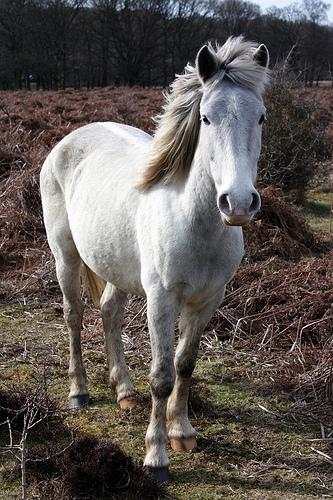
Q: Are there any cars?
A: No, there are no cars.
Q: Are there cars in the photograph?
A: No, there are no cars.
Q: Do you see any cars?
A: No, there are no cars.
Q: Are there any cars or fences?
A: No, there are no cars or fences.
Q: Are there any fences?
A: No, there are no fences.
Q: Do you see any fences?
A: No, there are no fences.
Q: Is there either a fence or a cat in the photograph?
A: No, there are no fences or cats.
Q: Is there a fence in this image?
A: No, there are no fences.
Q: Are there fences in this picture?
A: No, there are no fences.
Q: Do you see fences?
A: No, there are no fences.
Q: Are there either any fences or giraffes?
A: No, there are no fences or giraffes.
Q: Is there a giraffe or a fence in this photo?
A: No, there are no fences or giraffes.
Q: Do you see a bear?
A: No, there are no bears.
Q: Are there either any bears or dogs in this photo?
A: No, there are no bears or dogs.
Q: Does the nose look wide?
A: Yes, the nose is wide.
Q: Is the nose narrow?
A: No, the nose is wide.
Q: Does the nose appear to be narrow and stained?
A: No, the nose is stained but wide.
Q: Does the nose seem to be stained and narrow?
A: No, the nose is stained but wide.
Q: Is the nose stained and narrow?
A: No, the nose is stained but wide.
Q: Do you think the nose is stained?
A: Yes, the nose is stained.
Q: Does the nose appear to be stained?
A: Yes, the nose is stained.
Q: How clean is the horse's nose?
A: The nose is stained.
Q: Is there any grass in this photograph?
A: Yes, there is grass.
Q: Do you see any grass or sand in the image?
A: Yes, there is grass.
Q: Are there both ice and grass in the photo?
A: No, there is grass but no ice.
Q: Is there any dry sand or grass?
A: Yes, there is dry grass.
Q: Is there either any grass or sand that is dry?
A: Yes, the grass is dry.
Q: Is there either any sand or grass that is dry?
A: Yes, the grass is dry.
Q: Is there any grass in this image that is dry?
A: Yes, there is dry grass.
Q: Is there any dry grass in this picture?
A: Yes, there is dry grass.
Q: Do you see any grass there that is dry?
A: Yes, there is grass that is dry.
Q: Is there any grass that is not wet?
A: Yes, there is dry grass.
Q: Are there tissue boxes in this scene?
A: No, there are no tissue boxes.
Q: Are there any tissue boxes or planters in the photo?
A: No, there are no tissue boxes or planters.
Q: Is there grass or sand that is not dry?
A: No, there is grass but it is dry.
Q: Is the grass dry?
A: Yes, the grass is dry.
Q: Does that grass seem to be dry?
A: Yes, the grass is dry.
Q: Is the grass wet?
A: No, the grass is dry.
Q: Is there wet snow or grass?
A: No, there is grass but it is dry.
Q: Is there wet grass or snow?
A: No, there is grass but it is dry.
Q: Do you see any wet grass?
A: No, there is grass but it is dry.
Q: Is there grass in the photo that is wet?
A: No, there is grass but it is dry.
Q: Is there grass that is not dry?
A: No, there is grass but it is dry.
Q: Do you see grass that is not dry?
A: No, there is grass but it is dry.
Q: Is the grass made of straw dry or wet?
A: The grass is dry.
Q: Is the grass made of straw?
A: Yes, the grass is made of straw.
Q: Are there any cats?
A: No, there are no cats.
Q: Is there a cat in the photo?
A: No, there are no cats.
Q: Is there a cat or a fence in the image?
A: No, there are no cats or fences.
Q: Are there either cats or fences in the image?
A: No, there are no cats or fences.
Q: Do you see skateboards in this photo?
A: No, there are no skateboards.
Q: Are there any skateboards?
A: No, there are no skateboards.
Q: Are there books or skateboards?
A: No, there are no skateboards or books.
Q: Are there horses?
A: Yes, there is a horse.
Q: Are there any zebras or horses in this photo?
A: Yes, there is a horse.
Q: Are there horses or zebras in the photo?
A: Yes, there is a horse.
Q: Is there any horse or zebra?
A: Yes, there is a horse.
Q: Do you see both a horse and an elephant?
A: No, there is a horse but no elephants.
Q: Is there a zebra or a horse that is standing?
A: Yes, the horse is standing.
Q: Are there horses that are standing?
A: Yes, there is a horse that is standing.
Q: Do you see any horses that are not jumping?
A: Yes, there is a horse that is standing .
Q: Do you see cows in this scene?
A: No, there are no cows.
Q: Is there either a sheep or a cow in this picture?
A: No, there are no cows or sheep.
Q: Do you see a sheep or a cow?
A: No, there are no cows or sheep.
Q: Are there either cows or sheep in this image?
A: No, there are no cows or sheep.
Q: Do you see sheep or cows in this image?
A: No, there are no cows or sheep.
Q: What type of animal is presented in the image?
A: The animal is a horse.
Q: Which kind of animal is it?
A: The animal is a horse.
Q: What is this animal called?
A: This is a horse.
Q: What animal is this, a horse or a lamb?
A: This is a horse.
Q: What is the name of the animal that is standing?
A: The animal is a horse.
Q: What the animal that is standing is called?
A: The animal is a horse.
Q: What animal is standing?
A: The animal is a horse.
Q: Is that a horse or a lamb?
A: That is a horse.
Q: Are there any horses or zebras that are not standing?
A: No, there is a horse but it is standing.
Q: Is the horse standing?
A: Yes, the horse is standing.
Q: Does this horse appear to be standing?
A: Yes, the horse is standing.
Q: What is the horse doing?
A: The horse is standing.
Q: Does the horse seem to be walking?
A: No, the horse is standing.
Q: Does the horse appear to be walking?
A: No, the horse is standing.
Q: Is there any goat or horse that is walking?
A: No, there is a horse but it is standing.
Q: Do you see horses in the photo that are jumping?
A: No, there is a horse but it is standing.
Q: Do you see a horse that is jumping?
A: No, there is a horse but it is standing.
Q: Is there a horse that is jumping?
A: No, there is a horse but it is standing.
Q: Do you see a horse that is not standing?
A: No, there is a horse but it is standing.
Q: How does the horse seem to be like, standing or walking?
A: The horse is standing.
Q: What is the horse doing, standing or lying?
A: The horse is standing.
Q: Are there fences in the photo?
A: No, there are no fences.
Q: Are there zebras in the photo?
A: No, there are no zebras.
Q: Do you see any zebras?
A: No, there are no zebras.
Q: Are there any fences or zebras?
A: No, there are no zebras or fences.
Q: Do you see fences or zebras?
A: No, there are no zebras or fences.